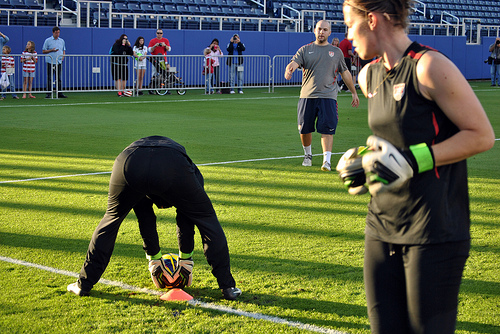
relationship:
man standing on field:
[66, 133, 244, 300] [7, 84, 499, 331]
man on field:
[283, 17, 360, 172] [7, 84, 499, 331]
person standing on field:
[327, 0, 498, 333] [7, 84, 499, 331]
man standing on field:
[283, 17, 360, 172] [7, 84, 499, 331]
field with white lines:
[7, 84, 499, 331] [4, 138, 361, 333]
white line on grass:
[10, 132, 296, 324] [4, 79, 496, 331]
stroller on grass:
[146, 54, 187, 97] [0, 84, 300, 104]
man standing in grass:
[66, 133, 244, 300] [4, 79, 496, 331]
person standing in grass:
[19, 38, 41, 100] [4, 79, 496, 331]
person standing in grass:
[42, 26, 68, 98] [4, 79, 496, 331]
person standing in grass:
[104, 30, 134, 95] [4, 79, 496, 331]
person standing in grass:
[132, 37, 147, 92] [2, 91, 288, 136]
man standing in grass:
[283, 17, 360, 172] [0, 79, 500, 333]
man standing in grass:
[283, 17, 360, 172] [261, 212, 325, 294]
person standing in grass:
[327, 0, 498, 333] [4, 79, 496, 331]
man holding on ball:
[62, 127, 247, 317] [152, 251, 192, 295]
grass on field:
[4, 79, 496, 331] [29, 106, 396, 271]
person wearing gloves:
[335, 0, 498, 333] [327, 125, 440, 202]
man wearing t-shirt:
[283, 17, 360, 172] [297, 40, 343, 102]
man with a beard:
[283, 17, 360, 172] [313, 35, 328, 45]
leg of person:
[402, 251, 461, 331] [335, 0, 498, 333]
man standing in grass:
[66, 133, 244, 300] [7, 114, 496, 330]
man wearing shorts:
[271, 17, 358, 125] [292, 97, 357, 129]